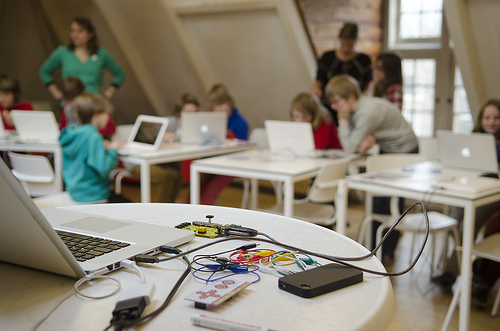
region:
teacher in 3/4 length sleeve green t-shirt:
[42, 15, 126, 101]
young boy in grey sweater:
[328, 74, 418, 153]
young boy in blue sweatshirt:
[55, 97, 122, 202]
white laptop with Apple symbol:
[432, 122, 496, 174]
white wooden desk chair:
[274, 159, 344, 225]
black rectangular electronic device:
[271, 259, 371, 302]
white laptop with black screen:
[114, 106, 170, 166]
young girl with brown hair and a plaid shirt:
[371, 52, 406, 112]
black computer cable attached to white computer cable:
[102, 257, 157, 329]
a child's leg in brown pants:
[155, 163, 181, 201]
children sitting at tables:
[68, 82, 499, 196]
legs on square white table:
[190, 146, 346, 214]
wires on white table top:
[101, 201, 432, 329]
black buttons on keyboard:
[48, 226, 125, 259]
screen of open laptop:
[119, 114, 170, 157]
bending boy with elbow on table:
[326, 77, 413, 160]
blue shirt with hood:
[60, 123, 117, 201]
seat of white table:
[359, 209, 456, 256]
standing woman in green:
[45, 15, 122, 108]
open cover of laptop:
[1, 163, 78, 278]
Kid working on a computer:
[59, 94, 132, 202]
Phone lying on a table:
[277, 261, 363, 298]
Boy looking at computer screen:
[326, 74, 419, 265]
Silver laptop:
[1, 158, 194, 282]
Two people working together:
[130, 85, 247, 202]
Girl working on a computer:
[433, 102, 499, 289]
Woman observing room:
[39, 17, 128, 103]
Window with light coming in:
[401, 1, 476, 135]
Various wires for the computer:
[32, 202, 429, 329]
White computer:
[266, 120, 321, 153]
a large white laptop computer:
[264, 115, 337, 165]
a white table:
[337, 154, 499, 329]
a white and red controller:
[184, 261, 260, 308]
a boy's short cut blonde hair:
[325, 73, 361, 105]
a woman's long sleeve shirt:
[38, 43, 125, 101]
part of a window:
[402, 61, 433, 133]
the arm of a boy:
[337, 118, 369, 151]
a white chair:
[11, 153, 56, 200]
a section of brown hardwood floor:
[390, 279, 486, 329]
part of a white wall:
[187, 20, 305, 123]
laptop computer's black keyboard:
[30, 223, 133, 265]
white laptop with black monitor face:
[118, 111, 173, 158]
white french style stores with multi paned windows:
[390, 48, 479, 137]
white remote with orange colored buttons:
[184, 271, 256, 307]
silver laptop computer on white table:
[1, 142, 198, 286]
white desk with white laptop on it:
[188, 133, 360, 235]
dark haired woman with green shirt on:
[37, 14, 125, 106]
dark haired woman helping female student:
[312, 14, 403, 129]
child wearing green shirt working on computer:
[58, 88, 175, 205]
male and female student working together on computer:
[262, 70, 418, 174]